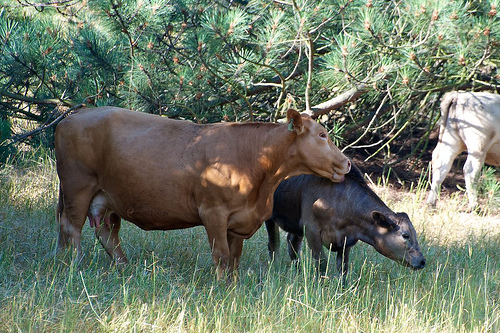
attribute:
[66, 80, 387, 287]
cow — brown, happy, grazing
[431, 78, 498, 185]
cow — white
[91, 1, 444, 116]
tree — pine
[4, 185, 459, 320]
grass — tall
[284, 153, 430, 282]
cow — baby